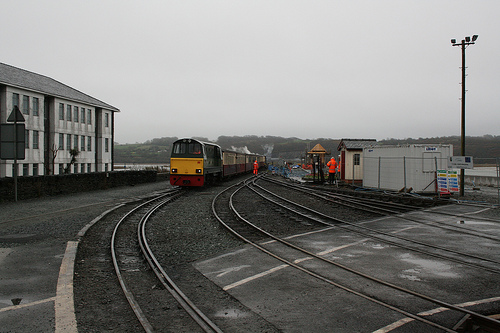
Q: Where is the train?
A: On the train tracks.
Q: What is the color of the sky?
A: Gray.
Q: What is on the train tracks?
A: A train.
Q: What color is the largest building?
A: White.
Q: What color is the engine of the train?
A: Yellow and red.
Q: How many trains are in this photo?
A: One.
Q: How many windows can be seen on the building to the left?
A: 26.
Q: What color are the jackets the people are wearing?
A: Orange.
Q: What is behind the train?
A: Trees.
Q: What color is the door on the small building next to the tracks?
A: Brown.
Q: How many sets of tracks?
A: 4.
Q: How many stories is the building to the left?
A: 3.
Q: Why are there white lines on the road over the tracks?
A: Crossing area for cars.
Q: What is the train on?
A: Tracks.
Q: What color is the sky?
A: Gray.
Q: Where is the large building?
A: Left of the train.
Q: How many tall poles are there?
A: One.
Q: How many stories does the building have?
A: Three.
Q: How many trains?
A: 1.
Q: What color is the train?
A: Yellow.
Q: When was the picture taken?
A: Daytime.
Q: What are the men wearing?
A: Orange suits.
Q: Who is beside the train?
A: The man.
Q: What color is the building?
A: White.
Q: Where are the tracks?
A: Under the train.